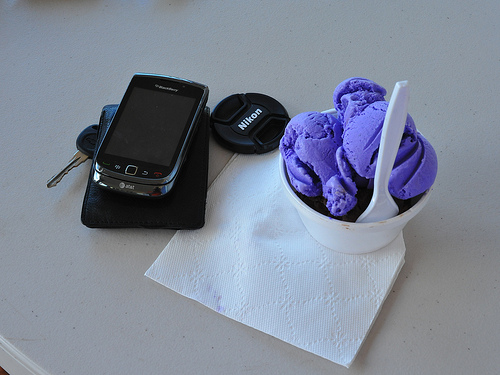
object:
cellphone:
[87, 69, 213, 199]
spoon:
[352, 78, 416, 223]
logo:
[118, 182, 135, 190]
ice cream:
[272, 75, 440, 219]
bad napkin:
[141, 142, 408, 370]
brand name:
[236, 107, 264, 131]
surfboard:
[0, 0, 500, 375]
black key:
[44, 123, 109, 190]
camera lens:
[207, 91, 294, 154]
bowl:
[277, 107, 441, 255]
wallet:
[79, 102, 212, 229]